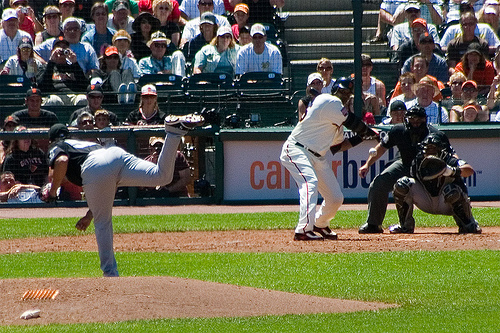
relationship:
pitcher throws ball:
[24, 132, 163, 272] [367, 145, 378, 161]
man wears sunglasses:
[232, 22, 293, 86] [246, 27, 268, 39]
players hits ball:
[277, 75, 364, 240] [367, 145, 378, 161]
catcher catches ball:
[381, 134, 482, 250] [367, 145, 378, 161]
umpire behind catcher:
[365, 87, 447, 234] [381, 134, 482, 250]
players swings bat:
[277, 75, 364, 240] [353, 97, 398, 155]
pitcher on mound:
[24, 132, 163, 272] [0, 276, 380, 324]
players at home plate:
[43, 74, 475, 266] [383, 213, 448, 250]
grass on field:
[193, 262, 405, 301] [356, 244, 499, 320]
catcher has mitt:
[381, 134, 482, 250] [404, 156, 456, 194]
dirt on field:
[340, 235, 437, 258] [356, 244, 499, 320]